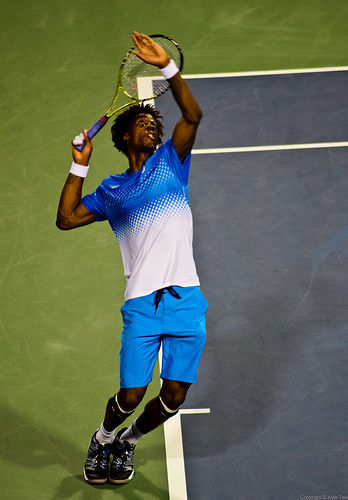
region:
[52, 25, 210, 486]
A man playing tennis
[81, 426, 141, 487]
Black, blue, and white athletic shoes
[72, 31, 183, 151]
A tennis racket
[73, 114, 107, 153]
The handle of the tennis racket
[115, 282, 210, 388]
A pair of blue shorts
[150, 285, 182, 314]
The black drawstring on blue shorts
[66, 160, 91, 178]
A white sweatband on the swinging arm of the man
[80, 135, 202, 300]
A blue and white shirt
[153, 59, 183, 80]
A white sweatband on the oppositie of the swinging hand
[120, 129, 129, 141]
The ear of the man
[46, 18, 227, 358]
black male tennis player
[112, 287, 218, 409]
bright blue long tennis shorts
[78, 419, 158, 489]
black tennis shoes with white ankle socks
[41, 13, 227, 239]
tennis player reaching overhead for ball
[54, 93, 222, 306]
man wearing blue and white tennis shirt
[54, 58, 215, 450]
man in blue and white tennis outfit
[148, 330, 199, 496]
out of bounds line on tennis court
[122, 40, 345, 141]
out of bounds line at back of tennis court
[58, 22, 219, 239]
tennis player wearing white wrist bands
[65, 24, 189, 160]
purple and neon green tennis racket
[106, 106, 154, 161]
man has dark hair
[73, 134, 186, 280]
blue and white shirt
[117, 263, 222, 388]
black and blue shorts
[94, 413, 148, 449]
player has white socks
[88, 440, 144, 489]
black and blue shoes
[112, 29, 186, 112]
black and yellow racket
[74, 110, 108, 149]
blue grip on racket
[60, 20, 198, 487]
Monfils standing behind baseline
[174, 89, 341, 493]
inner court is dark grey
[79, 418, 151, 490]
Tennis shoes on a man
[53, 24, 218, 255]
Upper torso of a man playing tennis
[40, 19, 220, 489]
A man in the middle of serving at tennis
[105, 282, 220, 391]
Blue shorts on a tennis player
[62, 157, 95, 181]
Wrist band on a man's right hand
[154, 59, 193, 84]
Wrist band on a man's left hand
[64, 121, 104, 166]
Hand grasping a tennis racquet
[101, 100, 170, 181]
Face of a man playing tennis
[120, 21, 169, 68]
The left hand of a man serving in tennis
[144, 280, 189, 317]
The tie of a man's shorts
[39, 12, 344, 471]
man playing tennis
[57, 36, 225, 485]
man about to hit return a tennis ball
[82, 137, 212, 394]
tennis player is wearing blue shorts and a blue and white shirt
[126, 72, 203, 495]
white line that divides the court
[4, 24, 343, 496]
grey and green tennis court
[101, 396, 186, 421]
player has sweat bands around both needs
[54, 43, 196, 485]
player is looking directly above him and reaching up to hit ball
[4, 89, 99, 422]
faded white looking scuff marks on court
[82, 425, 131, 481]
player is wearing black tennis shoes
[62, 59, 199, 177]
player is wearing two white sweat bands on his wrists